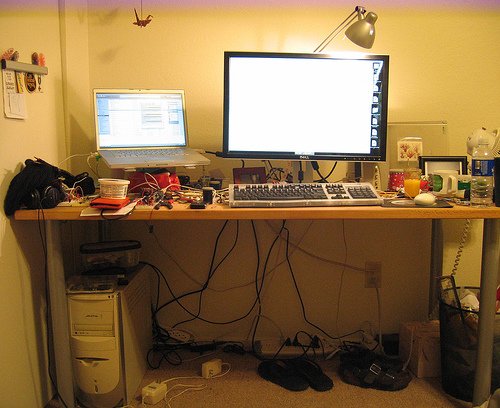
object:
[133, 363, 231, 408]
cables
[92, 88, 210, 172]
laptop computer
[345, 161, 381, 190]
speaker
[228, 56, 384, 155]
monitor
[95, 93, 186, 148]
monitor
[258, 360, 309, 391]
flip flop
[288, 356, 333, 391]
flip flop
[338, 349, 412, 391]
sandals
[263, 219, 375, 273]
cord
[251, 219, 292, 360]
cord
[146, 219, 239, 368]
cord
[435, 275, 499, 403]
can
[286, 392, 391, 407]
ground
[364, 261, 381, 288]
outlet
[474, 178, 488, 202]
water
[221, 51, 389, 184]
computer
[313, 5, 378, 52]
desk lamp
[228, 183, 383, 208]
keyboard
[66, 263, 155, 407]
computer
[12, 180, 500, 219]
table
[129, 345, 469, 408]
floor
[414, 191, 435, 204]
mouse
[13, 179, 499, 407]
desk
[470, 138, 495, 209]
bottle